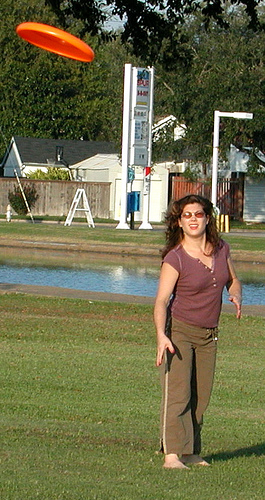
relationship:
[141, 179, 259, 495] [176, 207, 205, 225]
woman with sunglasses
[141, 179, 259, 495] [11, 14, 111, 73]
woman looking at frisbee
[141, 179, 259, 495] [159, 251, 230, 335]
woman wearing shirt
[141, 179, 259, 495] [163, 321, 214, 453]
woman wearing pants